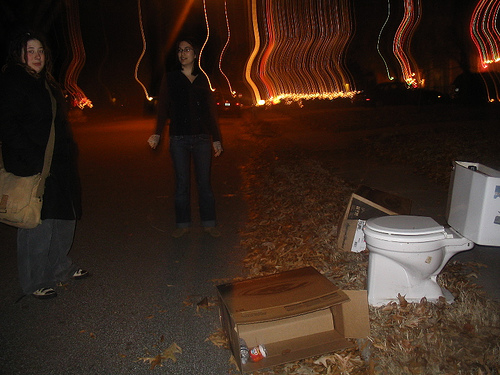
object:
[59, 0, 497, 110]
lights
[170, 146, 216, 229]
jeans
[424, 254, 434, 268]
spot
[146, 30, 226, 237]
woman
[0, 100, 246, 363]
road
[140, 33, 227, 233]
train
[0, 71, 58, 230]
bag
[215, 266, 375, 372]
trash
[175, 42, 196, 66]
head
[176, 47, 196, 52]
glasses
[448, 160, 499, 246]
tank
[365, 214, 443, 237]
seat lid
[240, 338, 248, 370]
bottle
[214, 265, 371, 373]
box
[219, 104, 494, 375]
sidewalks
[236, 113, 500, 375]
roadside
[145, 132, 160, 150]
right hand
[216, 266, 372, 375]
cardboard box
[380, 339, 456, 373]
leaves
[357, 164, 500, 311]
toilet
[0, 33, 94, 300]
person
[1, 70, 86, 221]
coat